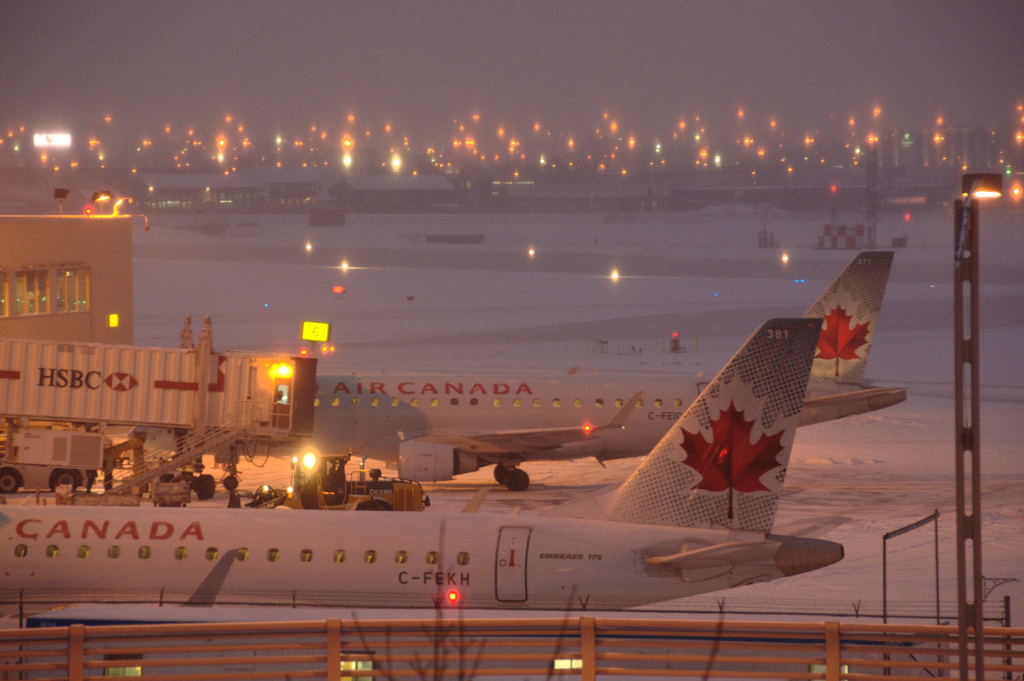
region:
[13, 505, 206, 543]
CANADA logo on white plane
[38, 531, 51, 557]
Window on the plane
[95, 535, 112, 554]
Window on the plane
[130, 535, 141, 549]
Window on the plane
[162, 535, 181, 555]
Window on the plane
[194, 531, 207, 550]
Window on the plane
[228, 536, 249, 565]
Window on the plane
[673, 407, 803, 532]
red leaf on plane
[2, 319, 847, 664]
white airplane that's landed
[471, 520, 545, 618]
door on the plane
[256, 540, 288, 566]
window on the airplane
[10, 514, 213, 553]
Canada written on plane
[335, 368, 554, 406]
air canada written on plane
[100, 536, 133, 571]
window on the plane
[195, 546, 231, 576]
window on the plane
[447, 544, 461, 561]
window on the plane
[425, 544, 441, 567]
window on the plane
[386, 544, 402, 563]
window on the plane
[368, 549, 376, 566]
window on the plane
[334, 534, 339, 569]
window on the plane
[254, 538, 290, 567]
window on the plane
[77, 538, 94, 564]
window on the plane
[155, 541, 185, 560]
window on the plane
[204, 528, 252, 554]
window on the plane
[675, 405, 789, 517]
Leaf logo on the tail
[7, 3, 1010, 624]
snow covering the ground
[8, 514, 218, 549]
Lettering on the plane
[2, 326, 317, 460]
Loading dock for the plane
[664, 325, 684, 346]
Red signal light on the ground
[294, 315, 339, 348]
Yellow lighted sign by the plane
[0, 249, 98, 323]
Windows in the building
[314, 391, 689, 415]
Windows on the plane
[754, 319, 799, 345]
number on the tail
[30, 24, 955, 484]
picture taken outdoors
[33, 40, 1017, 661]
picture taken at an airport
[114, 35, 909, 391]
heavy snow in the air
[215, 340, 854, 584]
two air canada planes on the tarmac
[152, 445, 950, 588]
the plane is white and red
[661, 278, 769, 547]
the tail has a red maple leaf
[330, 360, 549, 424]
plane says air canada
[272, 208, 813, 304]
lights lit on the runway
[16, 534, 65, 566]
windows on the side of an airplane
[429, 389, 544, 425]
windows on the side of an airplane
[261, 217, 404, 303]
lights on a runway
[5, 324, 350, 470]
passenger loading apparatus for an airplane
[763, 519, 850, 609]
silver tip of tail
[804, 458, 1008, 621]
white snow on runway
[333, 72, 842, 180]
orange lights in distance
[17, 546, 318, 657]
white wing on plane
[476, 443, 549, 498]
black wheels on plane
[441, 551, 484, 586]
a window on the plane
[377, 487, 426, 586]
a window on the plane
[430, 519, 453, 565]
a window on the plane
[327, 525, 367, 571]
a window on the plane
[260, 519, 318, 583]
a window on the plane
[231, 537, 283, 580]
a window on the plane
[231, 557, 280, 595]
a window on the plane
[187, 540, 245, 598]
a window on the plane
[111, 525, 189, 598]
a window on the plane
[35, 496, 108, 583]
a window on the plane